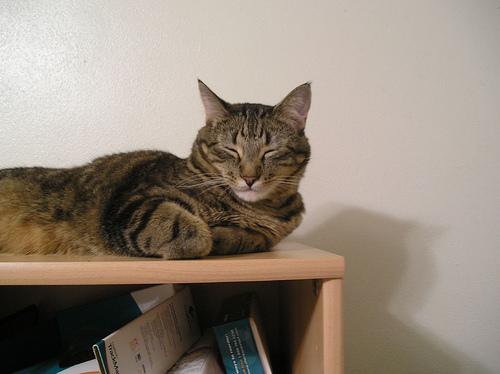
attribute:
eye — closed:
[217, 141, 240, 157]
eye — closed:
[258, 143, 278, 159]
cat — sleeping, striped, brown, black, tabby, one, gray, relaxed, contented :
[2, 76, 315, 260]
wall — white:
[45, 35, 153, 136]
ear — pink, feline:
[271, 82, 311, 119]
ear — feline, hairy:
[276, 82, 319, 122]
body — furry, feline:
[3, 163, 214, 243]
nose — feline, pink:
[238, 173, 259, 187]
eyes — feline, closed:
[222, 143, 282, 162]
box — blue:
[218, 309, 273, 372]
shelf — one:
[6, 280, 346, 370]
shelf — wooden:
[6, 264, 354, 291]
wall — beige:
[381, 36, 485, 281]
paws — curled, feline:
[135, 217, 262, 257]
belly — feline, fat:
[12, 216, 101, 254]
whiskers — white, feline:
[168, 167, 324, 196]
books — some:
[18, 296, 292, 369]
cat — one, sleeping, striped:
[6, 87, 334, 262]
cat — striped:
[13, 88, 312, 266]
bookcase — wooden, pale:
[4, 252, 347, 371]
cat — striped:
[30, 61, 320, 260]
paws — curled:
[140, 201, 255, 257]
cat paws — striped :
[134, 207, 288, 257]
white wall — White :
[1, 3, 496, 371]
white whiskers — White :
[191, 167, 291, 190]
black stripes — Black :
[112, 79, 319, 254]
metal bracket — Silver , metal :
[300, 273, 324, 310]